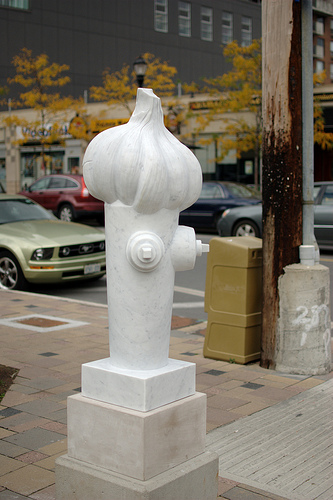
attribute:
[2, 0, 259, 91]
building — large, grey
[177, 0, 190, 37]
window — apart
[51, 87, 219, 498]
hydrant — white